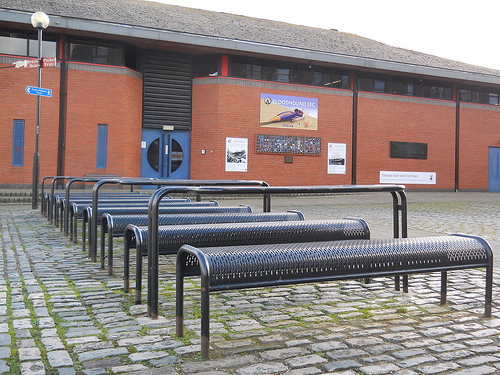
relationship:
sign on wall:
[241, 84, 335, 138] [201, 75, 428, 190]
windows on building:
[230, 57, 376, 91] [54, 5, 469, 179]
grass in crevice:
[41, 293, 63, 325] [50, 285, 65, 357]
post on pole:
[32, 75, 52, 113] [24, 23, 54, 208]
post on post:
[25, 86, 52, 99] [32, 75, 52, 113]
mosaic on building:
[249, 129, 325, 158] [54, 5, 469, 179]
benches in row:
[149, 216, 482, 318] [41, 170, 480, 344]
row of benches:
[41, 170, 480, 344] [149, 216, 482, 318]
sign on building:
[326, 136, 345, 178] [54, 5, 469, 179]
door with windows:
[136, 122, 193, 199] [152, 127, 186, 174]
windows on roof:
[230, 57, 376, 91] [0, 0, 500, 88]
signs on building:
[201, 75, 428, 190] [54, 5, 469, 179]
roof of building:
[13, 2, 488, 35] [54, 5, 469, 179]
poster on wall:
[219, 135, 252, 169] [201, 75, 428, 190]